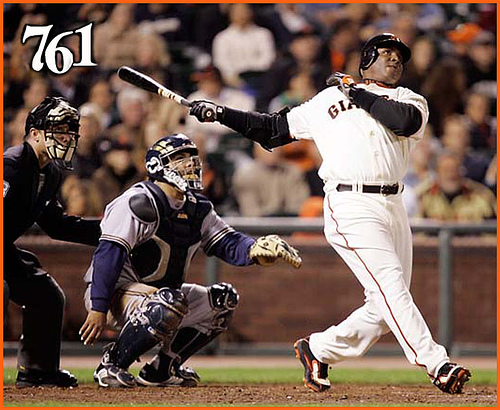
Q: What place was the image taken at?
A: It was taken at the stadium.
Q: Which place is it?
A: It is a stadium.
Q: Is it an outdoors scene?
A: Yes, it is outdoors.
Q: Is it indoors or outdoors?
A: It is outdoors.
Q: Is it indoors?
A: No, it is outdoors.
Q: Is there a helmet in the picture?
A: Yes, there is a helmet.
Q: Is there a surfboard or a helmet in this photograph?
A: Yes, there is a helmet.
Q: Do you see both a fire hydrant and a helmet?
A: No, there is a helmet but no fire hydrants.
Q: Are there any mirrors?
A: No, there are no mirrors.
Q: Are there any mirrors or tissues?
A: No, there are no mirrors or tissues.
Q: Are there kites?
A: No, there are no kites.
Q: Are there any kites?
A: No, there are no kites.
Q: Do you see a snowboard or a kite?
A: No, there are no kites or snowboards.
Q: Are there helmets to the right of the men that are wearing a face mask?
A: Yes, there are helmets to the right of the men.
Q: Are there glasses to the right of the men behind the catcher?
A: No, there are helmets to the right of the men.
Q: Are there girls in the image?
A: No, there are no girls.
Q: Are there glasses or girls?
A: No, there are no girls or glasses.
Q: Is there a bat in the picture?
A: Yes, there is a bat.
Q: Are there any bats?
A: Yes, there is a bat.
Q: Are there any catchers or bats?
A: Yes, there is a bat.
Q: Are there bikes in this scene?
A: No, there are no bikes.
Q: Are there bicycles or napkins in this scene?
A: No, there are no bicycles or napkins.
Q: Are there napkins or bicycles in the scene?
A: No, there are no bicycles or napkins.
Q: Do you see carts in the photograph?
A: No, there are no carts.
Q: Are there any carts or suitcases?
A: No, there are no carts or suitcases.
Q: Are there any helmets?
A: Yes, there is a helmet.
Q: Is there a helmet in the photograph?
A: Yes, there is a helmet.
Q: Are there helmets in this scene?
A: Yes, there is a helmet.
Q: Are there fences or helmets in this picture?
A: Yes, there is a helmet.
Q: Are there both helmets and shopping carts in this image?
A: No, there is a helmet but no shopping carts.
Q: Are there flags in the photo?
A: No, there are no flags.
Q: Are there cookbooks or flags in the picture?
A: No, there are no flags or cookbooks.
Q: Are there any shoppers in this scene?
A: No, there are no shoppers.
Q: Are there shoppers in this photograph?
A: No, there are no shoppers.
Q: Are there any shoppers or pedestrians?
A: No, there are no shoppers or pedestrians.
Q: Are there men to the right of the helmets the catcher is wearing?
A: Yes, there are men to the right of the helmets.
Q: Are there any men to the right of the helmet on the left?
A: Yes, there are men to the right of the helmet.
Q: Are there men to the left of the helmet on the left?
A: No, the men are to the right of the helmet.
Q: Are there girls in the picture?
A: No, there are no girls.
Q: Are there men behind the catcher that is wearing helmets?
A: Yes, there are men behind the catcher.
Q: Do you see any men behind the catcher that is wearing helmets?
A: Yes, there are men behind the catcher.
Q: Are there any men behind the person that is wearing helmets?
A: Yes, there are men behind the catcher.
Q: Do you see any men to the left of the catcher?
A: Yes, there are men to the left of the catcher.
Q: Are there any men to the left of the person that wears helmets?
A: Yes, there are men to the left of the catcher.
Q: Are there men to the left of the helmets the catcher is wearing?
A: Yes, there are men to the left of the helmets.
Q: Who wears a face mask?
A: The men wear a face mask.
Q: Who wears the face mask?
A: The men wear a face mask.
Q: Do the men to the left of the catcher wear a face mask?
A: Yes, the men wear a face mask.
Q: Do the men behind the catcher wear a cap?
A: No, the men wear a face mask.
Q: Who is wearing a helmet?
A: The men are wearing a helmet.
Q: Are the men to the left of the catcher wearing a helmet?
A: Yes, the men are wearing a helmet.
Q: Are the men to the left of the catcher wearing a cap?
A: No, the men are wearing a helmet.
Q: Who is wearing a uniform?
A: The men are wearing a uniform.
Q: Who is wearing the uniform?
A: The men are wearing a uniform.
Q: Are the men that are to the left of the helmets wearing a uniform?
A: Yes, the men are wearing a uniform.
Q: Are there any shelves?
A: No, there are no shelves.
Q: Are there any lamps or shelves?
A: No, there are no shelves or lamps.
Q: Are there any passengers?
A: No, there are no passengers.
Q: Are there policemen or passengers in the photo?
A: No, there are no passengers or policemen.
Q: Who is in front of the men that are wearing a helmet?
A: The catcher is in front of the men.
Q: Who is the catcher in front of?
A: The catcher is in front of the men.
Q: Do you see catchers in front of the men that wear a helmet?
A: Yes, there is a catcher in front of the men.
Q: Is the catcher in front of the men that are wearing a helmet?
A: Yes, the catcher is in front of the men.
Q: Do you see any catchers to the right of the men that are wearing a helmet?
A: Yes, there is a catcher to the right of the men.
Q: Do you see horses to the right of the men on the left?
A: No, there is a catcher to the right of the men.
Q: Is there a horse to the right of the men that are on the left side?
A: No, there is a catcher to the right of the men.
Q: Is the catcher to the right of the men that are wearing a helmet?
A: Yes, the catcher is to the right of the men.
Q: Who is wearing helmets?
A: The catcher is wearing helmets.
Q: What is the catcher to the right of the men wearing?
A: The catcher is wearing helmets.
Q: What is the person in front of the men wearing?
A: The catcher is wearing helmets.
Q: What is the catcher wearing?
A: The catcher is wearing helmets.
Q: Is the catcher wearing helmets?
A: Yes, the catcher is wearing helmets.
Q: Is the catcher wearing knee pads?
A: No, the catcher is wearing helmets.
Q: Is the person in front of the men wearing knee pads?
A: No, the catcher is wearing helmets.